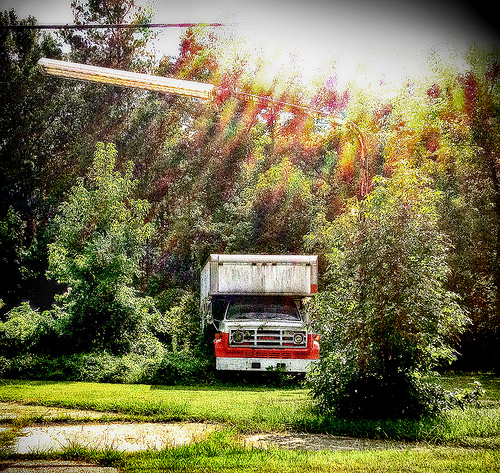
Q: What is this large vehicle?
A: Truck.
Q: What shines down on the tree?
A: Sunlight.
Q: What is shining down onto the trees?
A: Sunlight.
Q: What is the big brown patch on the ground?
A: Dirt.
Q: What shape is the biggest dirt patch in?
A: Circle.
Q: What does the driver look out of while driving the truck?
A: Windshield.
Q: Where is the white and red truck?
A: In the forest.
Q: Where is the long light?
A: On a pole.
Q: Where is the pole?
A: In a field.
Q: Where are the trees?
A: In the forest.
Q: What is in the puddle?
A: Water.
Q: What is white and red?
A: The truck.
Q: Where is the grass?
A: In the forest.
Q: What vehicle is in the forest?
A: A truck.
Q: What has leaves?
A: The tree.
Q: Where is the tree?
A: Next to the truck.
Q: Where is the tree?
A: In front of the truck.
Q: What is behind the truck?
A: The trees.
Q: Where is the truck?
A: In between the trees.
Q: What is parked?
A: The truck.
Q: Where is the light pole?
A: In the middle of the tree.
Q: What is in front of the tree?
A: The sidewalk.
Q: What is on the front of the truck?
A: Headlights.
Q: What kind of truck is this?
A: A Uhaul.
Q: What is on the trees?
A: Leaves.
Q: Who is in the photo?
A: No one.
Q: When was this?
A: Daytime.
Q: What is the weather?
A: Sunny.